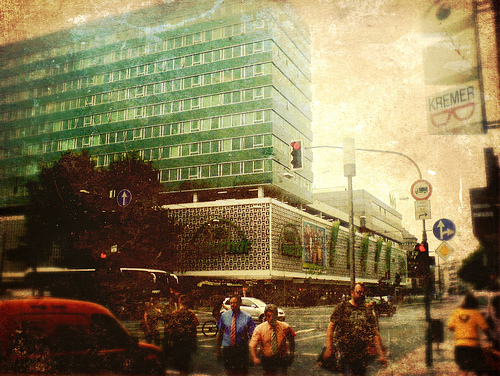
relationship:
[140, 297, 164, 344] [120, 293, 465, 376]
person in street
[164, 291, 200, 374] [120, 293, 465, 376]
person in street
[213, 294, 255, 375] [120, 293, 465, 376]
person in street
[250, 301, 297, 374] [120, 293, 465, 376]
person in street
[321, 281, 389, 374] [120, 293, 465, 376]
person in street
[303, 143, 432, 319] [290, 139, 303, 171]
pole holding traffic light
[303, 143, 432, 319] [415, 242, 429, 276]
pole holding traffic light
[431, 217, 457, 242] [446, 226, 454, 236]
sign has arrow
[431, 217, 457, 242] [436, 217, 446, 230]
sign has arrow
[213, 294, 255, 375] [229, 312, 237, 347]
person with tie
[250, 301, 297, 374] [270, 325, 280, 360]
person with tie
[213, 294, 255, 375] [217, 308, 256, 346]
person wearing shirt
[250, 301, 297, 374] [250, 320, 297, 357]
person wearing shirt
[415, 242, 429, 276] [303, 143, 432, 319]
traffic light on pole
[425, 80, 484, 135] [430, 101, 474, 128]
sign has glasses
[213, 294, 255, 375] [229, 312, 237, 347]
person wearing tie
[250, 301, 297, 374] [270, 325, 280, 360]
person wearing tie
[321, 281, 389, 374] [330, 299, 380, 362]
person in top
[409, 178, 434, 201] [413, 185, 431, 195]
sign with truck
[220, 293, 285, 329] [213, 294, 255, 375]
car behind person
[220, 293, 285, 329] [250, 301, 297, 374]
car behind person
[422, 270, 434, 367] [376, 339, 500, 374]
pole on sidewalk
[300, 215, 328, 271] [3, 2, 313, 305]
sign on building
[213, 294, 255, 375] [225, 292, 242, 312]
person has head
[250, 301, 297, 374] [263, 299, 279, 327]
person has head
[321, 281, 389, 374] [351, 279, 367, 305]
person has head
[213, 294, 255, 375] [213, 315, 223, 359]
person has arm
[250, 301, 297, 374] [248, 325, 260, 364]
person has arm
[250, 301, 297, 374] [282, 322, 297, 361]
person has arm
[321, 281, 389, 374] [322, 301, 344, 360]
person has arm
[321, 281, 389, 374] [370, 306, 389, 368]
person has arm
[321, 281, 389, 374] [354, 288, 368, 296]
person wearing sunglasses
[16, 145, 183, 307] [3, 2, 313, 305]
tree in front of building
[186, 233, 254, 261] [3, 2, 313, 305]
name on building